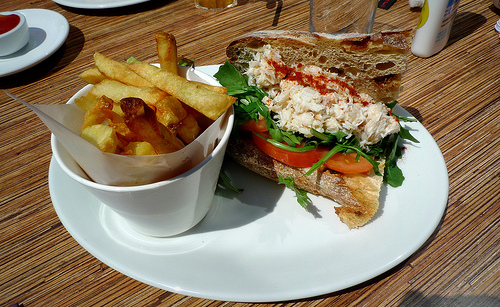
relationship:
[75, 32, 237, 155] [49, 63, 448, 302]
fries are on top of plate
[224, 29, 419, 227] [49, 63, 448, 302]
sandwich on top of plate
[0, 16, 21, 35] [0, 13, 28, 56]
ketchup inside bowl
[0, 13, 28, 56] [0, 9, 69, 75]
bowl on top of plate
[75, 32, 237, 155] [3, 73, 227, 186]
fries are inside of paper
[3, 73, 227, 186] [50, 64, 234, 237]
paper inside of bowl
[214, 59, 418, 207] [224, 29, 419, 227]
lettuce inside of sandwich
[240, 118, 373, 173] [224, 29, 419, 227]
tomatoes are inside of sandwich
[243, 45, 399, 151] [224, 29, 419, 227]
meat inside of sandwich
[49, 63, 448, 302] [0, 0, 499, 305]
plate on top of table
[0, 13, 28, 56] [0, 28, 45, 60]
bowl has reflection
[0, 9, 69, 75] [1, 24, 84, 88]
plate has reflection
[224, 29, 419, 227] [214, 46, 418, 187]
sandwich has filling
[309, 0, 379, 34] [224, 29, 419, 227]
bottle behind sandwich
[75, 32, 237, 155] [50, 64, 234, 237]
fries are inside of bowl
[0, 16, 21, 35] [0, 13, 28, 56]
ketchup inside of bowl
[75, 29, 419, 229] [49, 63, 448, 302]
lunch on top of plate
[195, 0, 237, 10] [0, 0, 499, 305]
glass on top of table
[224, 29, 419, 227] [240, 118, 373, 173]
sandwich has tomatoes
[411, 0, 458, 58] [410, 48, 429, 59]
bottle has edge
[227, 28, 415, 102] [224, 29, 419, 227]
bread on top of sandwich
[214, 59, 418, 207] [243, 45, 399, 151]
lettuce below meat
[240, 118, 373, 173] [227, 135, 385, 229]
tomatoes are on top of bread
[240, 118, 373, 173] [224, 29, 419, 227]
tomatoes are on top of sandwich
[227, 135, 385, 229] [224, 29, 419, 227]
bread below sandwich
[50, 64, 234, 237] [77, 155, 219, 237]
bowl has front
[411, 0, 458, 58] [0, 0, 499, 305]
bottle on top of table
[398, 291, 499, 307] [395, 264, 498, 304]
shadow on bottom right